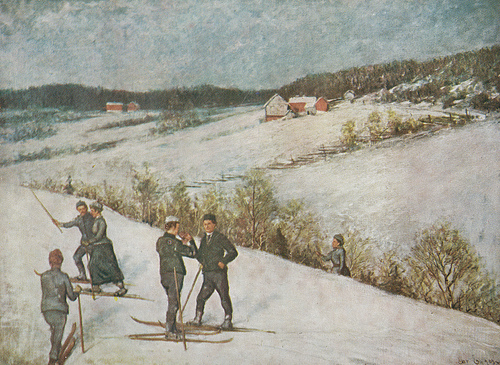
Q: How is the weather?
A: It is cloudy.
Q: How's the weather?
A: It is cloudy.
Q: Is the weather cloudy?
A: Yes, it is cloudy.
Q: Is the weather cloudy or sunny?
A: It is cloudy.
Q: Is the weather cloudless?
A: No, it is cloudy.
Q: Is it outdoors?
A: Yes, it is outdoors.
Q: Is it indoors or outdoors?
A: It is outdoors.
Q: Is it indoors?
A: No, it is outdoors.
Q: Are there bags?
A: No, there are no bags.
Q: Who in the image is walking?
A: The people are walking.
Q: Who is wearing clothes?
A: The people are wearing clothes.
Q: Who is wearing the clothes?
A: The people are wearing clothes.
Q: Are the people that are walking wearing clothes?
A: Yes, the people are wearing clothes.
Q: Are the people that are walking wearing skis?
A: No, the people are wearing clothes.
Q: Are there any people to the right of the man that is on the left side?
A: Yes, there are people to the right of the man.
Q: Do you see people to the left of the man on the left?
A: No, the people are to the right of the man.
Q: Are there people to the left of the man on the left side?
A: No, the people are to the right of the man.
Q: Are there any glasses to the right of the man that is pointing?
A: No, there are people to the right of the man.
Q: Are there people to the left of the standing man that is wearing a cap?
A: Yes, there are people to the left of the man.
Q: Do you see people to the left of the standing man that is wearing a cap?
A: Yes, there are people to the left of the man.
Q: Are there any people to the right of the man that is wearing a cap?
A: No, the people are to the left of the man.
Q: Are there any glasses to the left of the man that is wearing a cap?
A: No, there are people to the left of the man.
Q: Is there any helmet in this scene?
A: No, there are no helmets.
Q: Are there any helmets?
A: No, there are no helmets.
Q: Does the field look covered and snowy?
A: Yes, the field is covered and snowy.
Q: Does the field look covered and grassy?
A: No, the field is covered but snowy.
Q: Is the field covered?
A: Yes, the field is covered.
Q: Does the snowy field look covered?
A: Yes, the field is covered.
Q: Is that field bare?
A: No, the field is covered.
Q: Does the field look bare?
A: No, the field is covered.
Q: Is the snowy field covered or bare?
A: The field is covered.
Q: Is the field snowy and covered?
A: Yes, the field is snowy and covered.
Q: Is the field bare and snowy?
A: No, the field is snowy but covered.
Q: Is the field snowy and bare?
A: No, the field is snowy but covered.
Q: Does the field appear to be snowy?
A: Yes, the field is snowy.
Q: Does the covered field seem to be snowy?
A: Yes, the field is snowy.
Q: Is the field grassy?
A: No, the field is snowy.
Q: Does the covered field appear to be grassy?
A: No, the field is snowy.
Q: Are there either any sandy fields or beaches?
A: No, there is a field but it is snowy.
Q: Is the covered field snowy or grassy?
A: The field is snowy.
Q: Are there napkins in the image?
A: No, there are no napkins.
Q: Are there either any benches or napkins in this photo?
A: No, there are no napkins or benches.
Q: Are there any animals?
A: No, there are no animals.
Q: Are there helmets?
A: No, there are no helmets.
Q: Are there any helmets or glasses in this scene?
A: No, there are no helmets or glasses.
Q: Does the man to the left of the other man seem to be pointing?
A: Yes, the man is pointing.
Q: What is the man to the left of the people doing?
A: The man is pointing.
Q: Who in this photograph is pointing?
A: The man is pointing.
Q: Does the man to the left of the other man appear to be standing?
A: No, the man is pointing.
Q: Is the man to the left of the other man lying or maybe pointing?
A: The man is pointing.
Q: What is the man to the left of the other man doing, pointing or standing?
A: The man is pointing.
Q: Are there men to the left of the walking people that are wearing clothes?
A: Yes, there is a man to the left of the people.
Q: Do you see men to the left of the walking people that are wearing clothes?
A: Yes, there is a man to the left of the people.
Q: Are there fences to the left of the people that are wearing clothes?
A: No, there is a man to the left of the people.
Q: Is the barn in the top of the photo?
A: Yes, the barn is in the top of the image.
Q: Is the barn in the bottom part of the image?
A: No, the barn is in the top of the image.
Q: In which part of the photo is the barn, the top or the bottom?
A: The barn is in the top of the image.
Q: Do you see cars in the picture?
A: No, there are no cars.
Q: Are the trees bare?
A: Yes, the trees are bare.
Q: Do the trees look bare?
A: Yes, the trees are bare.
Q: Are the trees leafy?
A: No, the trees are bare.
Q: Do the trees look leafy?
A: No, the trees are bare.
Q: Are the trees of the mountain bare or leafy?
A: The trees are bare.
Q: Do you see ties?
A: No, there are no ties.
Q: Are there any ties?
A: No, there are no ties.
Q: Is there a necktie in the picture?
A: No, there are no ties.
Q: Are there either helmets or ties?
A: No, there are no ties or helmets.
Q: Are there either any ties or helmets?
A: No, there are no ties or helmets.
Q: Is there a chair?
A: No, there are no chairs.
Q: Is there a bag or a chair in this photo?
A: No, there are no chairs or bags.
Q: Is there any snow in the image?
A: Yes, there is snow.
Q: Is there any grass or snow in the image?
A: Yes, there is snow.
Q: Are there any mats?
A: No, there are no mats.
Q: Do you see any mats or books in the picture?
A: No, there are no mats or books.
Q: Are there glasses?
A: No, there are no glasses.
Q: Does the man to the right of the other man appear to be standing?
A: Yes, the man is standing.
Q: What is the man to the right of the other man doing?
A: The man is standing.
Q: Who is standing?
A: The man is standing.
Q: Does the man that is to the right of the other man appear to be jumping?
A: No, the man is standing.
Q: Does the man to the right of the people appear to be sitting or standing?
A: The man is standing.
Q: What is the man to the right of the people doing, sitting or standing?
A: The man is standing.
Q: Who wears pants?
A: The man wears pants.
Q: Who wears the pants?
A: The man wears pants.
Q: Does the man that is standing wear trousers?
A: Yes, the man wears trousers.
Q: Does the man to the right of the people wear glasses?
A: No, the man wears trousers.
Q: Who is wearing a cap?
A: The man is wearing a cap.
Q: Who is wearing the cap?
A: The man is wearing a cap.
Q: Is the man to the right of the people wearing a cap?
A: Yes, the man is wearing a cap.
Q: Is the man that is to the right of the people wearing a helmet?
A: No, the man is wearing a cap.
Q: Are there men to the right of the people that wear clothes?
A: Yes, there is a man to the right of the people.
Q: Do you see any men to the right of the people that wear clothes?
A: Yes, there is a man to the right of the people.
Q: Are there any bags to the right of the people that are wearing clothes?
A: No, there is a man to the right of the people.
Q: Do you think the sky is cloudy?
A: Yes, the sky is cloudy.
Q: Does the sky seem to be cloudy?
A: Yes, the sky is cloudy.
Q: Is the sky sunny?
A: No, the sky is cloudy.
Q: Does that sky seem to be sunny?
A: No, the sky is cloudy.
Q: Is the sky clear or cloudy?
A: The sky is cloudy.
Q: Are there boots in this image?
A: Yes, there are boots.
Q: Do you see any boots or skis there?
A: Yes, there are boots.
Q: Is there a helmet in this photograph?
A: No, there are no helmets.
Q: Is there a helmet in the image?
A: No, there are no helmets.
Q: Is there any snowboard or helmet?
A: No, there are no helmets or snowboards.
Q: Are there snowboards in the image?
A: No, there are no snowboards.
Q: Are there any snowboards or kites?
A: No, there are no snowboards or kites.